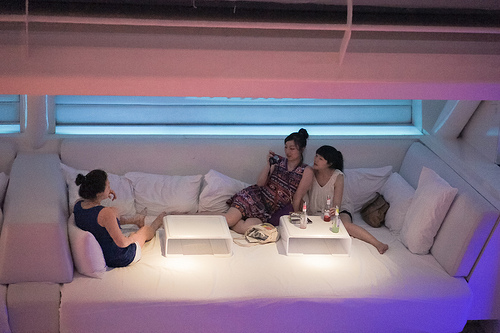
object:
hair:
[72, 167, 110, 201]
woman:
[302, 148, 392, 255]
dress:
[304, 168, 344, 216]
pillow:
[67, 212, 107, 277]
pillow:
[125, 173, 200, 215]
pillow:
[197, 171, 250, 217]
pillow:
[339, 166, 389, 211]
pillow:
[378, 170, 416, 228]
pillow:
[398, 163, 459, 254]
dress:
[73, 201, 137, 269]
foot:
[378, 241, 389, 256]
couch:
[4, 135, 492, 330]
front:
[108, 265, 444, 305]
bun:
[74, 173, 87, 187]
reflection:
[57, 121, 420, 141]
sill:
[54, 119, 426, 140]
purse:
[362, 195, 391, 228]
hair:
[312, 143, 346, 173]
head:
[312, 144, 335, 172]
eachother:
[218, 125, 391, 260]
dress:
[227, 158, 311, 223]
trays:
[160, 210, 235, 258]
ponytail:
[300, 128, 310, 139]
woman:
[66, 161, 174, 275]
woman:
[219, 124, 317, 244]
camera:
[269, 155, 280, 165]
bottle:
[323, 194, 332, 222]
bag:
[244, 223, 280, 246]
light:
[133, 245, 201, 278]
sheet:
[61, 225, 461, 328]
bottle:
[299, 201, 308, 230]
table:
[280, 210, 353, 256]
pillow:
[67, 161, 141, 221]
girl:
[289, 141, 391, 257]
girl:
[223, 124, 315, 245]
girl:
[63, 161, 164, 272]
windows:
[0, 94, 432, 138]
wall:
[2, 101, 484, 137]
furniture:
[3, 135, 493, 331]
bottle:
[330, 205, 343, 234]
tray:
[279, 216, 353, 256]